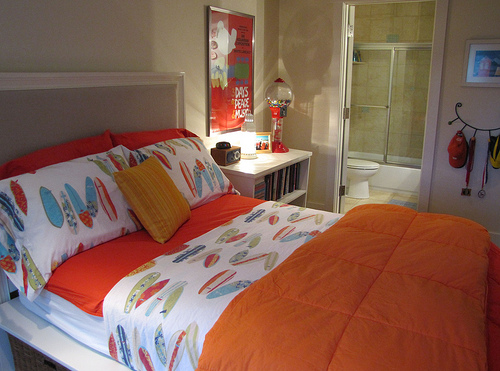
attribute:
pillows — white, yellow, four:
[96, 155, 210, 199]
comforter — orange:
[377, 235, 411, 259]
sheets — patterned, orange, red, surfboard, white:
[214, 246, 260, 270]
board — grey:
[14, 73, 176, 131]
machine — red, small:
[266, 69, 303, 150]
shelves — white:
[238, 154, 296, 175]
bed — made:
[7, 107, 459, 344]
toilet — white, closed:
[344, 156, 373, 195]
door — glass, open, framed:
[353, 36, 379, 138]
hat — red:
[447, 146, 471, 172]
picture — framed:
[454, 34, 498, 92]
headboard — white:
[140, 69, 173, 84]